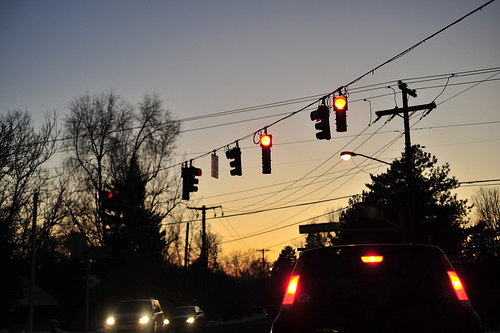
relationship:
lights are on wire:
[98, 94, 351, 215] [0, 41, 500, 200]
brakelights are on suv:
[266, 231, 484, 316] [266, 239, 492, 319]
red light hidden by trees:
[99, 185, 122, 229] [3, 94, 497, 304]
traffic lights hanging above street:
[165, 86, 367, 211] [58, 310, 498, 330]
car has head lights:
[158, 297, 218, 330] [160, 314, 194, 331]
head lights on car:
[160, 314, 194, 331] [158, 297, 218, 330]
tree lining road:
[335, 141, 480, 239] [210, 308, 270, 330]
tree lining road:
[63, 92, 188, 292] [210, 308, 270, 330]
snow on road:
[194, 299, 267, 331] [205, 307, 265, 328]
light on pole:
[99, 188, 113, 213] [114, 160, 131, 325]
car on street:
[103, 297, 165, 332] [211, 311, 268, 331]